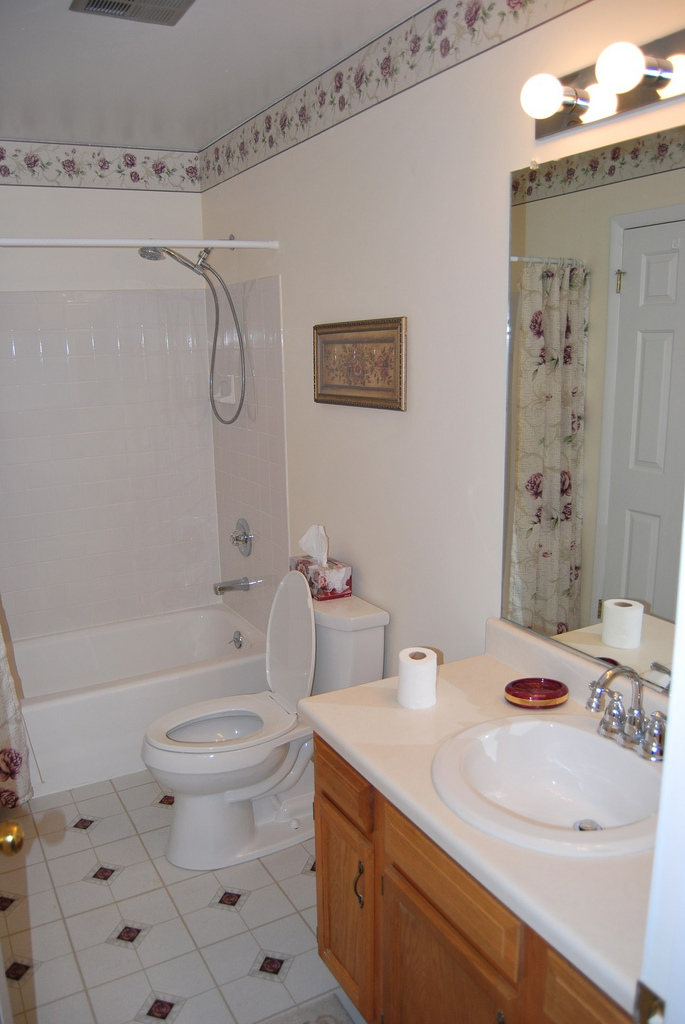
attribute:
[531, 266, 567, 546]
shower curtain — flowered , white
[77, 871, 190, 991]
tile — on the ground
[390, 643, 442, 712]
toilet paper — white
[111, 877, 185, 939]
tile — square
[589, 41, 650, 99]
light — round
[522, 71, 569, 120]
light — round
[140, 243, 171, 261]
nozzle — silver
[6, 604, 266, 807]
bathtub — white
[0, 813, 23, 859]
knob — round, gold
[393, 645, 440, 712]
paper roll — white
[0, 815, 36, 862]
knob — golden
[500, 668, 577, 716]
soap dish — red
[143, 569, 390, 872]
toilet — white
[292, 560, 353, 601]
flowers — red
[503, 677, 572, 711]
bowl — red, gold, circular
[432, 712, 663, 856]
sink — white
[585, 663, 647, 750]
faucet — silver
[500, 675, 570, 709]
dish — red, gold